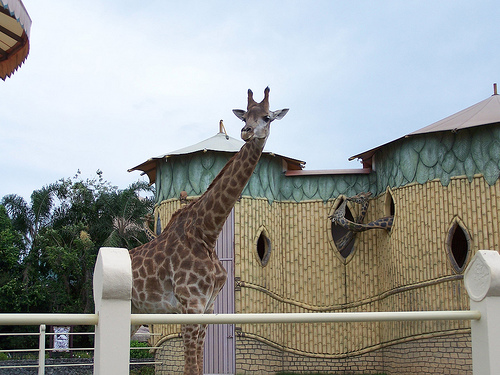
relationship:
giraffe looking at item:
[128, 87, 288, 369] [1, 2, 31, 86]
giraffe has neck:
[128, 87, 288, 369] [199, 142, 256, 237]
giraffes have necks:
[331, 193, 394, 259] [343, 221, 392, 258]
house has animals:
[140, 121, 500, 364] [331, 193, 394, 259]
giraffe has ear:
[128, 87, 288, 369] [227, 102, 293, 120]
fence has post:
[5, 244, 498, 374] [37, 324, 47, 375]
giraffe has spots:
[128, 87, 288, 369] [164, 231, 181, 260]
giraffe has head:
[328, 192, 371, 260] [344, 189, 371, 216]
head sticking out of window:
[344, 189, 371, 216] [328, 196, 358, 255]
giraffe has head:
[128, 87, 288, 369] [344, 189, 371, 216]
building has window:
[140, 121, 500, 364] [328, 196, 358, 255]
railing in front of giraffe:
[2, 298, 498, 333] [128, 87, 288, 369]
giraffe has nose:
[128, 87, 288, 369] [239, 127, 254, 134]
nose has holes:
[239, 127, 254, 134] [244, 126, 252, 132]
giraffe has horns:
[128, 87, 288, 369] [244, 88, 273, 104]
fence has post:
[5, 244, 498, 374] [36, 324, 45, 374]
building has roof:
[140, 121, 500, 364] [127, 123, 291, 161]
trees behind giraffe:
[1, 189, 137, 319] [128, 87, 288, 369]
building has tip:
[140, 121, 500, 364] [213, 118, 227, 137]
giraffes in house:
[331, 193, 394, 259] [140, 121, 500, 364]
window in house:
[328, 196, 358, 255] [140, 121, 500, 364]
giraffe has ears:
[128, 87, 288, 369] [227, 102, 293, 120]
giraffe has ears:
[128, 87, 288, 369] [232, 107, 287, 119]